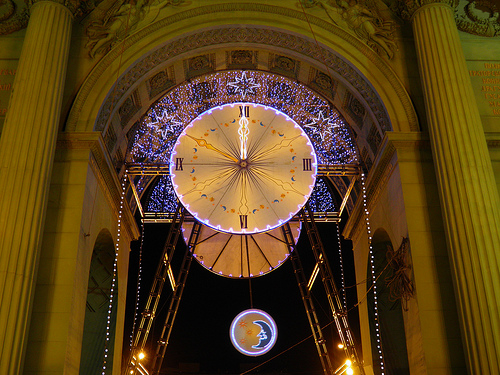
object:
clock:
[169, 102, 319, 234]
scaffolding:
[119, 203, 368, 375]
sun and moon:
[228, 308, 280, 358]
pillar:
[401, 1, 499, 374]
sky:
[120, 210, 364, 374]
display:
[131, 67, 361, 165]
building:
[0, 0, 499, 374]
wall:
[39, 0, 450, 270]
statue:
[85, 0, 194, 59]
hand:
[184, 133, 239, 164]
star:
[230, 72, 263, 101]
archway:
[71, 24, 427, 373]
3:
[300, 157, 315, 173]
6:
[238, 211, 253, 230]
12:
[237, 104, 251, 120]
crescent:
[227, 308, 276, 354]